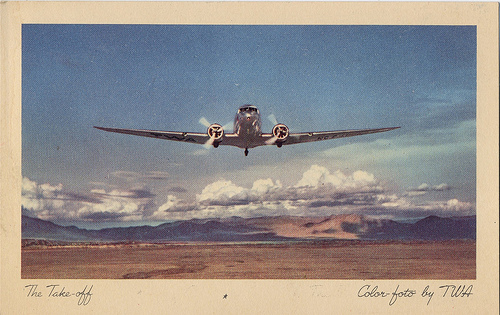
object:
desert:
[143, 244, 336, 278]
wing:
[260, 118, 402, 150]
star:
[204, 287, 241, 312]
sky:
[23, 22, 478, 229]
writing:
[23, 283, 473, 305]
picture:
[21, 25, 475, 279]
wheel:
[236, 146, 252, 161]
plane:
[94, 104, 399, 159]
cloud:
[337, 172, 380, 205]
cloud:
[286, 165, 346, 207]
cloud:
[251, 171, 298, 208]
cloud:
[197, 174, 267, 214]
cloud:
[157, 179, 214, 228]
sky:
[224, 41, 390, 111]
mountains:
[22, 211, 477, 243]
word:
[346, 278, 397, 305]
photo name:
[23, 281, 95, 307]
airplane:
[85, 100, 404, 157]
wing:
[90, 113, 229, 160]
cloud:
[407, 180, 454, 192]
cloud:
[195, 163, 384, 203]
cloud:
[87, 182, 157, 197]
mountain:
[408, 212, 475, 236]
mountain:
[257, 210, 415, 240]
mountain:
[152, 220, 263, 237]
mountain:
[23, 214, 99, 239]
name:
[355, 281, 476, 304]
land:
[20, 245, 475, 283]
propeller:
[262, 111, 301, 151]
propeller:
[195, 115, 240, 150]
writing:
[19, 279, 101, 314]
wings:
[89, 124, 405, 144]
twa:
[148, 130, 198, 143]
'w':
[167, 132, 180, 144]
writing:
[303, 136, 361, 141]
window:
[235, 105, 259, 115]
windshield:
[239, 106, 256, 115]